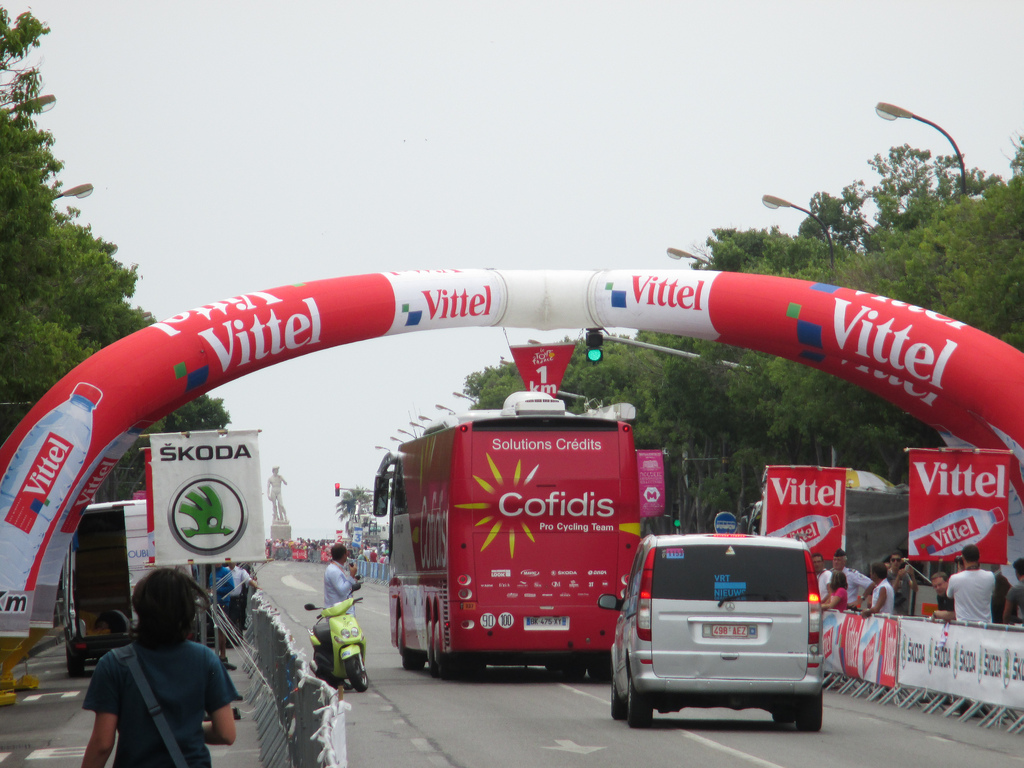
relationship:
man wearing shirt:
[805, 526, 912, 714] [834, 560, 882, 641]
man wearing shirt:
[829, 538, 910, 686] [805, 536, 918, 677]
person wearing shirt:
[55, 562, 252, 767] [80, 627, 236, 764]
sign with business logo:
[131, 374, 283, 563] [132, 404, 264, 577]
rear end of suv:
[581, 486, 871, 755] [583, 519, 843, 733]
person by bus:
[55, 562, 252, 767] [356, 340, 670, 736]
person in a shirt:
[77, 567, 238, 766] [83, 644, 241, 766]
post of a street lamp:
[906, 113, 967, 153] [865, 98, 905, 125]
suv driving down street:
[583, 519, 843, 733] [336, 579, 1021, 767]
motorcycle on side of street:
[308, 595, 367, 688] [262, 549, 1023, 766]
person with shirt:
[55, 562, 252, 767] [83, 644, 241, 766]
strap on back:
[113, 640, 191, 757] [83, 651, 235, 762]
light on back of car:
[809, 579, 825, 618] [599, 526, 828, 723]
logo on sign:
[178, 471, 235, 538] [150, 428, 261, 560]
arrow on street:
[548, 729, 598, 766] [262, 549, 1023, 766]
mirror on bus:
[368, 467, 397, 522] [373, 394, 646, 665]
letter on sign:
[234, 325, 256, 369] [1, 266, 1023, 649]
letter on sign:
[250, 320, 268, 360] [1, 270, 1023, 582]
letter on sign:
[284, 311, 317, 361] [1, 270, 1023, 582]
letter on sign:
[424, 281, 451, 325] [1, 270, 1023, 582]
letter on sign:
[625, 266, 649, 310] [1, 270, 1023, 582]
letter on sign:
[904, 338, 937, 386] [1, 270, 1023, 582]